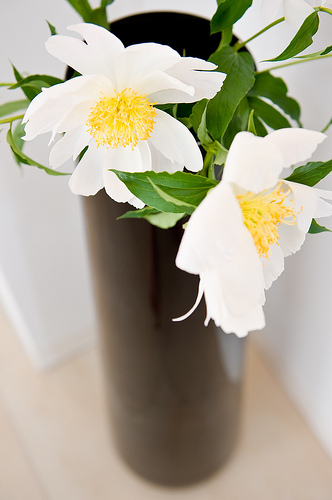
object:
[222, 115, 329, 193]
petals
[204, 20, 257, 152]
leaves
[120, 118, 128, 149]
stamens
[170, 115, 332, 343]
flowers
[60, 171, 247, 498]
vase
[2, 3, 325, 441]
wall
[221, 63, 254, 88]
green